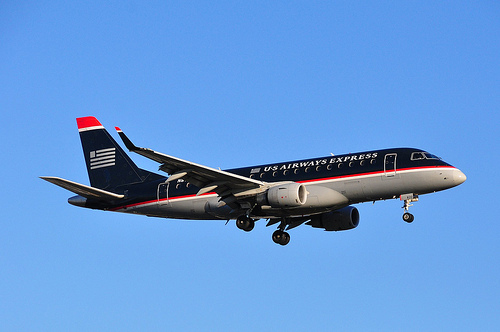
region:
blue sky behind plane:
[180, 32, 317, 103]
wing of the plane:
[125, 135, 255, 220]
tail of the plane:
[70, 95, 135, 185]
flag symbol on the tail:
[80, 135, 120, 175]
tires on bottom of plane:
[220, 195, 295, 265]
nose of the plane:
[430, 150, 475, 195]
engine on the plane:
[270, 175, 310, 215]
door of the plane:
[370, 140, 410, 180]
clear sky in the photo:
[240, 250, 395, 315]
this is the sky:
[190, 45, 301, 133]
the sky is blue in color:
[206, 32, 306, 112]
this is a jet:
[35, 112, 462, 247]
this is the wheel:
[402, 208, 416, 228]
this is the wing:
[134, 140, 244, 201]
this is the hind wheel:
[263, 231, 290, 255]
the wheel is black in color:
[273, 234, 288, 244]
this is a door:
[383, 150, 400, 175]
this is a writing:
[262, 160, 302, 172]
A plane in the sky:
[1, 2, 499, 330]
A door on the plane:
[375, 145, 400, 176]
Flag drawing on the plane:
[82, 143, 117, 173]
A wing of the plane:
[110, 119, 265, 203]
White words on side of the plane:
[260, 149, 380, 173]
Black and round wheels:
[231, 208, 295, 250]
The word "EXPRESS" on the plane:
[325, 150, 380, 165]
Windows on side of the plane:
[172, 154, 380, 191]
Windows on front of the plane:
[406, 145, 446, 165]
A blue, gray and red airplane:
[33, 112, 472, 249]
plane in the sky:
[63, 68, 493, 279]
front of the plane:
[428, 129, 488, 209]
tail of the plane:
[54, 108, 120, 198]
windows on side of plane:
[300, 153, 383, 181]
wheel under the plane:
[383, 200, 432, 240]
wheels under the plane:
[201, 205, 301, 275]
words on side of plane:
[250, 143, 392, 169]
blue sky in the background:
[233, 62, 359, 127]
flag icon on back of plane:
[71, 135, 126, 190]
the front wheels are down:
[396, 211, 415, 225]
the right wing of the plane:
[109, 117, 276, 201]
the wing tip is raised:
[111, 121, 134, 152]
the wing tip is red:
[115, 119, 124, 134]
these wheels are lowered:
[233, 212, 290, 252]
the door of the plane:
[380, 151, 399, 180]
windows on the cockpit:
[405, 149, 440, 164]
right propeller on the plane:
[260, 186, 312, 208]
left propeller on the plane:
[317, 204, 362, 231]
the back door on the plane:
[153, 180, 172, 206]